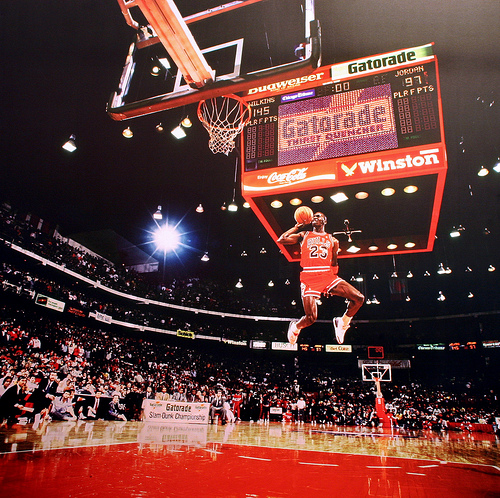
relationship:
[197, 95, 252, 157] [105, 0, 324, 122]
net and backboard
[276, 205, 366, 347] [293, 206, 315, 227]
player shooting basketball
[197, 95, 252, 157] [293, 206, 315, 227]
net for basketball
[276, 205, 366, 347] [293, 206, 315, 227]
player holding basketball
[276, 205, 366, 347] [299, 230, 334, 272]
player wearing jersey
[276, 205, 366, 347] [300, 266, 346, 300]
player wearing shorts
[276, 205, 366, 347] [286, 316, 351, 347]
player wearing shoes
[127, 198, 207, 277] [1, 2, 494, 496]
light in stadium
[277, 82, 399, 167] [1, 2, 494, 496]
advertisement in stadium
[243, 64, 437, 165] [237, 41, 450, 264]
scoreboard on jumbo tron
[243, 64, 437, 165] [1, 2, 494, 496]
scoreboard in stadium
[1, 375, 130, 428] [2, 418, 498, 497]
people on court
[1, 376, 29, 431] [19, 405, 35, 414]
man holding papers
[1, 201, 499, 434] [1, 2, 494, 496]
crowd in stadium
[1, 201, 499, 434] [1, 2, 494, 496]
crowd at stadium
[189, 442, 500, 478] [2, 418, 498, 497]
markings on court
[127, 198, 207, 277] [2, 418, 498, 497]
light on court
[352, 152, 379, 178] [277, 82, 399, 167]
letter on advertisement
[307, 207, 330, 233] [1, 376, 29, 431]
head of man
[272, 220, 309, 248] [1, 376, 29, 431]
arm of man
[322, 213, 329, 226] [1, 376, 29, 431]
ear of man